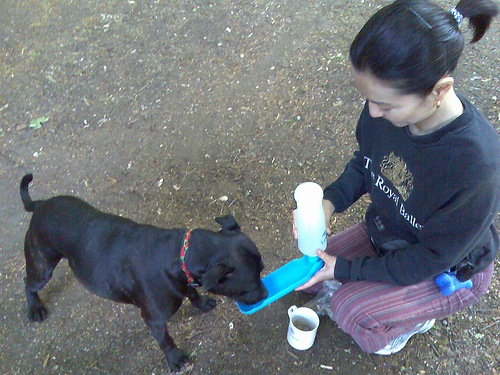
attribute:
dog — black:
[15, 164, 269, 357]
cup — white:
[280, 301, 320, 349]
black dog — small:
[19, 172, 268, 373]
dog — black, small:
[16, 165, 273, 374]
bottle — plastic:
[295, 175, 334, 264]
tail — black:
[5, 158, 64, 228]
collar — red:
[179, 229, 194, 291]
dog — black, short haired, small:
[14, 173, 265, 365]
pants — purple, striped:
[324, 218, 494, 353]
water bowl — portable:
[233, 180, 328, 316]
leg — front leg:
[139, 304, 195, 374]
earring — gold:
[436, 98, 443, 108]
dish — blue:
[234, 250, 323, 314]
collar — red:
[176, 226, 196, 286]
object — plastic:
[436, 273, 478, 299]